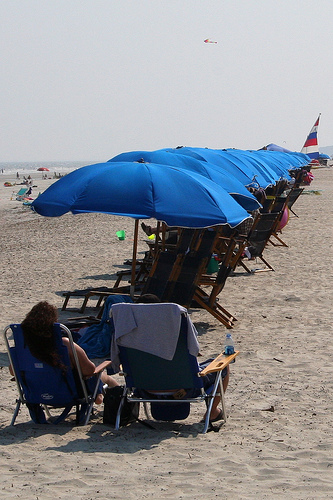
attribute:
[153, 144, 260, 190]
umbrella — blue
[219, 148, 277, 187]
umbrella — blue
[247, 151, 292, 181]
umbrella — blue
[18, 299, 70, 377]
hair — long, brown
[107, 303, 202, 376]
shirt — gray, grey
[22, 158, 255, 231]
umbrella — blue, open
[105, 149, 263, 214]
umbrella — blue, open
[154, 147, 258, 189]
umbrella — blue, open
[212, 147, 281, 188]
umbrella — blue, open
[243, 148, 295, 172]
umbrella — blue, open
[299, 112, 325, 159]
sail — red, white, blue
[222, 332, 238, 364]
water bottle — plastic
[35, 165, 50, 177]
umbrella — red, open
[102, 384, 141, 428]
bag — black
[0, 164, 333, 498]
ground — sandy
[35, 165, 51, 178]
umbrella — distant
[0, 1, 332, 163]
sky — blue, clear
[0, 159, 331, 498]
sand — brown, light brown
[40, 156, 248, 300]
umbrella — blue